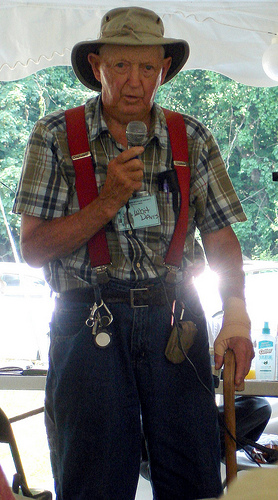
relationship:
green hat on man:
[58, 5, 195, 98] [13, 7, 254, 498]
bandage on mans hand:
[213, 298, 249, 357] [213, 295, 255, 383]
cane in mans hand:
[222, 345, 236, 484] [213, 295, 255, 383]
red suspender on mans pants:
[65, 102, 107, 272] [44, 279, 222, 499]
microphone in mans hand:
[124, 119, 149, 154] [89, 146, 143, 206]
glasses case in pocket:
[156, 160, 185, 230] [157, 192, 187, 233]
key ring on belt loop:
[85, 298, 110, 333] [89, 287, 103, 306]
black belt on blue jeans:
[48, 284, 193, 313] [44, 281, 224, 500]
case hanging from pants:
[165, 320, 198, 362] [44, 279, 222, 499]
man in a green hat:
[13, 7, 254, 498] [68, 5, 191, 94]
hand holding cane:
[213, 295, 255, 383] [222, 345, 236, 484]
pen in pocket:
[160, 178, 168, 201] [155, 186, 190, 236]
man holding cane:
[13, 7, 254, 498] [222, 345, 236, 493]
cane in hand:
[222, 345, 236, 484] [211, 315, 256, 387]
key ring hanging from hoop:
[85, 298, 113, 333] [92, 283, 100, 308]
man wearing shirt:
[13, 7, 254, 498] [13, 94, 247, 288]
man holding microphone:
[13, 7, 254, 498] [122, 118, 148, 211]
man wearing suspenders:
[13, 7, 254, 498] [162, 105, 188, 277]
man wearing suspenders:
[13, 7, 254, 498] [60, 100, 116, 272]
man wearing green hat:
[13, 7, 254, 498] [68, 5, 191, 94]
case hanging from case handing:
[165, 320, 197, 365] [171, 300, 185, 325]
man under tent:
[13, 7, 254, 498] [1, 0, 72, 74]